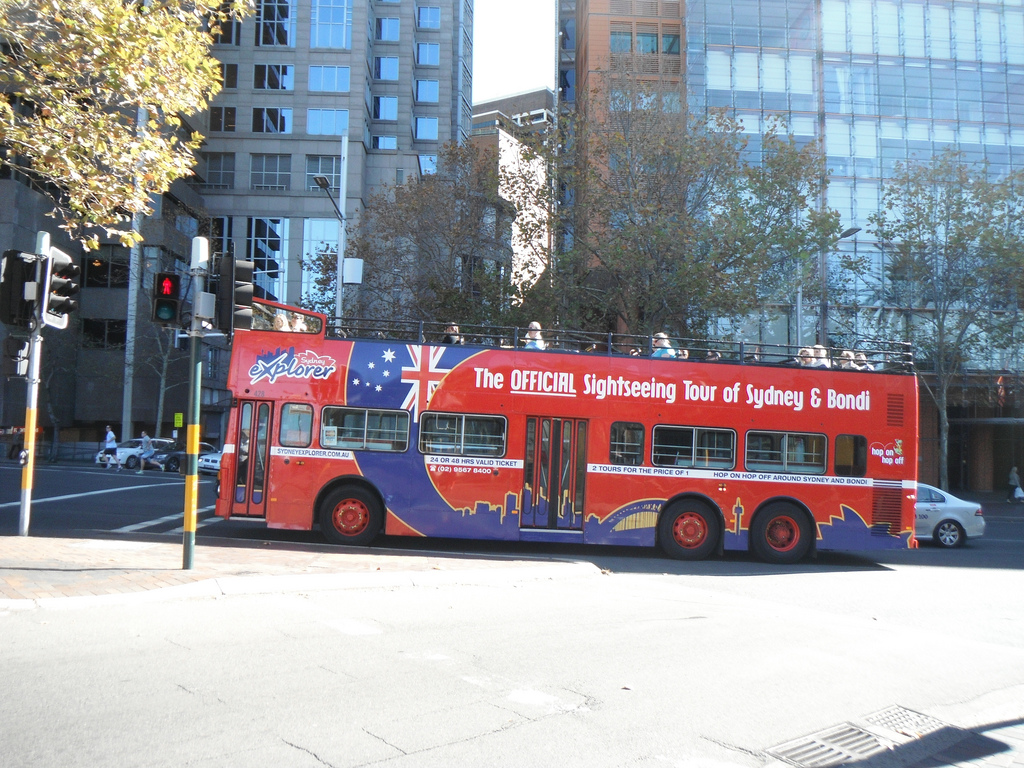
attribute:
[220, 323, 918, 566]
bus — red, blue, public, long, double decker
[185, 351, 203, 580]
post — metal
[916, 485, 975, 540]
car — grey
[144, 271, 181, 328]
crosswalk light — red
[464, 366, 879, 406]
writing — white